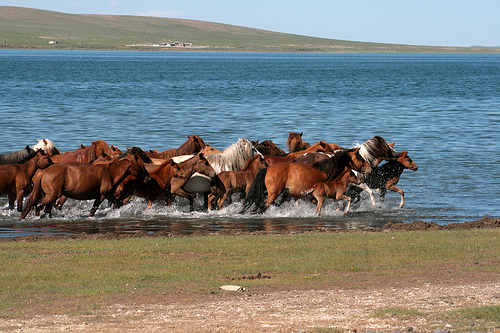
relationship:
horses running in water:
[16, 126, 428, 231] [261, 69, 441, 117]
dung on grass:
[231, 267, 274, 280] [1, 224, 498, 313]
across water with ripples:
[0, 46, 499, 217] [285, 88, 367, 122]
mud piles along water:
[3, 216, 499, 236] [0, 46, 499, 237]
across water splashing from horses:
[0, 46, 499, 217] [2, 129, 432, 226]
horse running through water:
[366, 149, 413, 215] [0, 46, 499, 237]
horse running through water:
[242, 147, 369, 217] [0, 46, 499, 237]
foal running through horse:
[301, 167, 361, 217] [366, 149, 413, 215]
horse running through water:
[282, 124, 314, 155] [0, 46, 499, 237]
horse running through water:
[17, 152, 153, 222] [0, 46, 499, 237]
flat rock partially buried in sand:
[218, 284, 244, 292] [4, 279, 497, 331]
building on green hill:
[47, 38, 56, 45] [0, 0, 499, 52]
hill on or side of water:
[2, 7, 306, 52] [1, 47, 499, 216]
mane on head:
[354, 137, 381, 169] [364, 131, 401, 160]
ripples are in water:
[56, 78, 161, 130] [7, 50, 483, 146]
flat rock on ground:
[218, 284, 244, 292] [52, 282, 467, 328]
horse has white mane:
[172, 136, 266, 175] [206, 135, 253, 172]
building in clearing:
[151, 41, 193, 48] [2, 34, 499, 53]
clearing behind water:
[2, 34, 499, 53] [0, 46, 499, 237]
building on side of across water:
[154, 39, 191, 49] [0, 46, 499, 217]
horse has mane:
[315, 134, 402, 213] [358, 134, 397, 167]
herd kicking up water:
[3, 128, 419, 211] [30, 194, 457, 216]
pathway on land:
[163, 277, 489, 330] [3, 220, 498, 330]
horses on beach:
[2, 129, 432, 226] [0, 219, 498, 330]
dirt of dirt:
[2, 285, 496, 330] [2, 285, 496, 330]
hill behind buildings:
[0, 0, 499, 52] [153, 42, 198, 51]